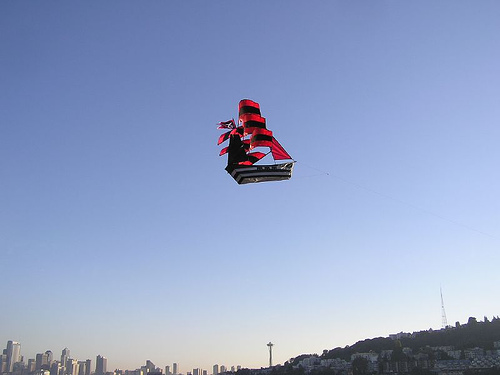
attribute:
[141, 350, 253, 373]
building building — small, middle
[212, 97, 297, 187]
kite — flying, red, black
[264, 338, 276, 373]
ride — tall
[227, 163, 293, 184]
boat base — black, white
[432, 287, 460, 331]
tower — cell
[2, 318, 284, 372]
skyline — city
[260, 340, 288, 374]
light — street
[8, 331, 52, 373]
buildings — tall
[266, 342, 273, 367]
tower — metal, tall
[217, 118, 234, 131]
flag — red, black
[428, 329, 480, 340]
bushes — bunch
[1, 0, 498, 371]
sky — clear, blue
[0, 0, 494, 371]
blue skies — clear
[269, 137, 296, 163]
sail — red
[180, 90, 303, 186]
kite — pirate ship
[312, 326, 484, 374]
houses — many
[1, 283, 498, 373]
city — below